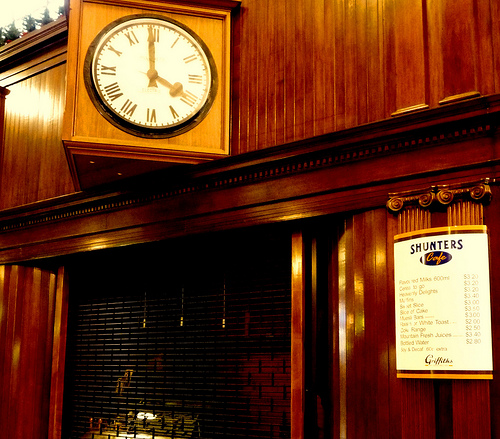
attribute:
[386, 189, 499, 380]
menu — white, cafe, laminated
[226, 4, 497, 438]
wall — wood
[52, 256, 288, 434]
gate — metal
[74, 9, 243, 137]
clock — saying, white, wood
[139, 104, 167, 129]
number — six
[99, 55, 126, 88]
nine — roman 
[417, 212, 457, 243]
line — yellow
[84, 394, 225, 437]
fireplace — closed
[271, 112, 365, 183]
mantle — empty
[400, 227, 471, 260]
word — written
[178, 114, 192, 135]
frame — round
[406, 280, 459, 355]
writing — black